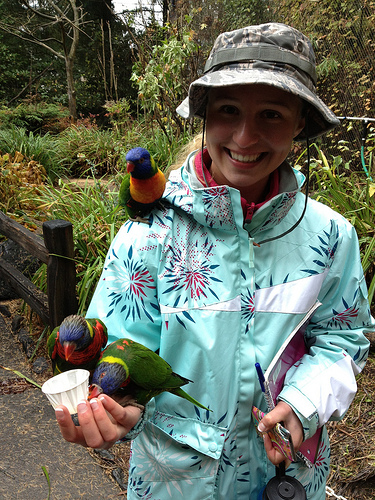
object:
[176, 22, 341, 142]
hat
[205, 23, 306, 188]
head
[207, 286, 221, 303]
design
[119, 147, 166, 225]
bird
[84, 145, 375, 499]
coat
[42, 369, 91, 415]
paper cup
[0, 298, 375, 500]
grey ground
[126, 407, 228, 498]
pocket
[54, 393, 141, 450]
hand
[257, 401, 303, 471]
hand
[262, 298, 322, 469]
book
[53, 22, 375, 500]
girl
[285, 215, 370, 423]
arm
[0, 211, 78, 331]
fence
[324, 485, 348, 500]
white chain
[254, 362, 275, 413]
ink pen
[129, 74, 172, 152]
plants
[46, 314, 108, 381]
bird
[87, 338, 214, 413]
bird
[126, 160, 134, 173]
beak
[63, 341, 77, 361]
beak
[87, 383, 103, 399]
beak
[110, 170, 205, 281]
shoulder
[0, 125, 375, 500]
ground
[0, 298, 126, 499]
stone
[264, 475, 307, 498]
black lid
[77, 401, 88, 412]
nail